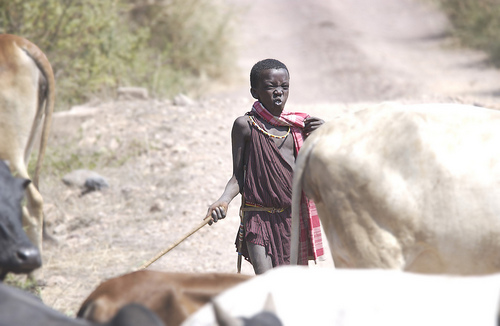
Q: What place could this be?
A: It is a road.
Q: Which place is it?
A: It is a road.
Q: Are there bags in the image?
A: No, there are no bags.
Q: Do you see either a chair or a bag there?
A: No, there are no bags or chairs.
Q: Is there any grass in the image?
A: Yes, there is grass.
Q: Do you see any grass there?
A: Yes, there is grass.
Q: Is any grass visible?
A: Yes, there is grass.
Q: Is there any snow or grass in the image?
A: Yes, there is grass.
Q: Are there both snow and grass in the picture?
A: No, there is grass but no snow.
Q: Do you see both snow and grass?
A: No, there is grass but no snow.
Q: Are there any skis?
A: No, there are no skis.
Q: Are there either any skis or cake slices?
A: No, there are no skis or cake slices.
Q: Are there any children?
A: Yes, there is a child.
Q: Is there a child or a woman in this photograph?
A: Yes, there is a child.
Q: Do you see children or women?
A: Yes, there is a child.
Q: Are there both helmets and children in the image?
A: No, there is a child but no helmets.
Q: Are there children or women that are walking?
A: Yes, the child is walking.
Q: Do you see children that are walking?
A: Yes, there is a child that is walking.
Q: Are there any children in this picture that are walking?
A: Yes, there is a child that is walking.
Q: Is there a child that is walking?
A: Yes, there is a child that is walking.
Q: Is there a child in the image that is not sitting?
A: Yes, there is a child that is walking.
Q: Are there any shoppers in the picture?
A: No, there are no shoppers.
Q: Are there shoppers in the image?
A: No, there are no shoppers.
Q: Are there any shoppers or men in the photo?
A: No, there are no shoppers or men.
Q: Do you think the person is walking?
A: Yes, the child is walking.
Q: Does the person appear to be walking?
A: Yes, the child is walking.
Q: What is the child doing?
A: The child is walking.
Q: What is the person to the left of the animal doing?
A: The child is walking.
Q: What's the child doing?
A: The child is walking.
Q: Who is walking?
A: The child is walking.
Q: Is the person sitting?
A: No, the kid is walking.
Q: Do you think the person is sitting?
A: No, the kid is walking.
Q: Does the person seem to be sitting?
A: No, the kid is walking.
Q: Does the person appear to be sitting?
A: No, the kid is walking.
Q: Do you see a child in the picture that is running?
A: No, there is a child but he is walking.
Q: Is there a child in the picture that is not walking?
A: No, there is a child but he is walking.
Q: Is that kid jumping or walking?
A: The kid is walking.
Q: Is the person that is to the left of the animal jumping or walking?
A: The kid is walking.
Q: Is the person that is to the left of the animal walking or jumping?
A: The kid is walking.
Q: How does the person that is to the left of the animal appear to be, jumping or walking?
A: The kid is walking.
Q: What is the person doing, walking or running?
A: The child is walking.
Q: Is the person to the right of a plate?
A: No, the kid is to the right of the cow.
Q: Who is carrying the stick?
A: The child is carrying the stick.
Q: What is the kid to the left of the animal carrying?
A: The kid is carrying a stick.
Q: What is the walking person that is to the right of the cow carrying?
A: The kid is carrying a stick.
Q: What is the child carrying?
A: The kid is carrying a stick.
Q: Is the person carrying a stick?
A: Yes, the kid is carrying a stick.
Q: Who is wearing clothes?
A: The kid is wearing clothes.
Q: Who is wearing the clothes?
A: The kid is wearing clothes.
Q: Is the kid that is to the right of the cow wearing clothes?
A: Yes, the child is wearing clothes.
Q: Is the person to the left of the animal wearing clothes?
A: Yes, the child is wearing clothes.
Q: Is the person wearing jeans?
A: No, the child is wearing clothes.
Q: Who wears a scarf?
A: The child wears a scarf.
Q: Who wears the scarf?
A: The child wears a scarf.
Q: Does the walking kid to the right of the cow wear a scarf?
A: Yes, the kid wears a scarf.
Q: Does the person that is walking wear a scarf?
A: Yes, the kid wears a scarf.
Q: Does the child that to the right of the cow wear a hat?
A: No, the child wears a scarf.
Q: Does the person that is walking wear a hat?
A: No, the child wears a scarf.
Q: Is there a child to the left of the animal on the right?
A: Yes, there is a child to the left of the animal.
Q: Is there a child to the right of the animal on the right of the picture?
A: No, the child is to the left of the animal.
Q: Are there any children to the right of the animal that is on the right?
A: No, the child is to the left of the animal.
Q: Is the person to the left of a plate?
A: No, the child is to the left of the animal.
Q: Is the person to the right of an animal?
A: No, the child is to the left of an animal.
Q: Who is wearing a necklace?
A: The kid is wearing a necklace.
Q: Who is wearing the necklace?
A: The kid is wearing a necklace.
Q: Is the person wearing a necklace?
A: Yes, the kid is wearing a necklace.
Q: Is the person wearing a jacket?
A: No, the child is wearing a necklace.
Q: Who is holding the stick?
A: The kid is holding the stick.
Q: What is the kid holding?
A: The kid is holding the stick.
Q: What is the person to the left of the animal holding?
A: The kid is holding the stick.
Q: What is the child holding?
A: The kid is holding the stick.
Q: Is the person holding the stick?
A: Yes, the kid is holding the stick.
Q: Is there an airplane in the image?
A: No, there are no airplanes.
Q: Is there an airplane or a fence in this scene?
A: No, there are no airplanes or fences.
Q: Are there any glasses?
A: No, there are no glasses.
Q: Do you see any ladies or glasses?
A: No, there are no glasses or ladies.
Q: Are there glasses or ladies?
A: No, there are no glasses or ladies.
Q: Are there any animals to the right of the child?
A: Yes, there is an animal to the right of the child.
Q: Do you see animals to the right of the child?
A: Yes, there is an animal to the right of the child.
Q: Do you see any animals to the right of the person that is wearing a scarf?
A: Yes, there is an animal to the right of the child.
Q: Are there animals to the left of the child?
A: No, the animal is to the right of the child.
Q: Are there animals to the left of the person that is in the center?
A: No, the animal is to the right of the child.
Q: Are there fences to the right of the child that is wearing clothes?
A: No, there is an animal to the right of the child.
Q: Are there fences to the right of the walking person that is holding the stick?
A: No, there is an animal to the right of the child.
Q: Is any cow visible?
A: Yes, there is a cow.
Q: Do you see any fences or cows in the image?
A: Yes, there is a cow.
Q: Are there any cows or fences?
A: Yes, there is a cow.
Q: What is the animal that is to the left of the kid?
A: The animal is a cow.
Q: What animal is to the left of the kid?
A: The animal is a cow.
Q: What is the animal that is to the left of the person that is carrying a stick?
A: The animal is a cow.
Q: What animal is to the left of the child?
A: The animal is a cow.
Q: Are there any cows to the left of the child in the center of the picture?
A: Yes, there is a cow to the left of the kid.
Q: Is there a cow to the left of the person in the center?
A: Yes, there is a cow to the left of the kid.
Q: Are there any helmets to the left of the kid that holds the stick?
A: No, there is a cow to the left of the kid.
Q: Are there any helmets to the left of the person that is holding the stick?
A: No, there is a cow to the left of the kid.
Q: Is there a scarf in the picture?
A: Yes, there is a scarf.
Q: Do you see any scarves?
A: Yes, there is a scarf.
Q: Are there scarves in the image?
A: Yes, there is a scarf.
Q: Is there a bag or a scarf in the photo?
A: Yes, there is a scarf.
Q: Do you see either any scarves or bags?
A: Yes, there is a scarf.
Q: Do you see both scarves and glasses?
A: No, there is a scarf but no glasses.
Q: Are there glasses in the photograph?
A: No, there are no glasses.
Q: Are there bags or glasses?
A: No, there are no glasses or bags.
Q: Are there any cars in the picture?
A: No, there are no cars.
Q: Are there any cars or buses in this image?
A: No, there are no cars or buses.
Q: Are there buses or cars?
A: No, there are no cars or buses.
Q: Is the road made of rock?
A: Yes, the road is made of rock.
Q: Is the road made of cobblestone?
A: No, the road is made of rock.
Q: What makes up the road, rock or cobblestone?
A: The road is made of rock.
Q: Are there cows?
A: Yes, there is a cow.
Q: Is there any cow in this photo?
A: Yes, there is a cow.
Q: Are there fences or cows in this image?
A: Yes, there is a cow.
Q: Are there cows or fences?
A: Yes, there is a cow.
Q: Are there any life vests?
A: No, there are no life vests.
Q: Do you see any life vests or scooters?
A: No, there are no life vests or scooters.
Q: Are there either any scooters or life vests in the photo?
A: No, there are no life vests or scooters.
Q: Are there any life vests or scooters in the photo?
A: No, there are no life vests or scooters.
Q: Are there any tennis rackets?
A: No, there are no tennis rackets.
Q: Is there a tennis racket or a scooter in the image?
A: No, there are no rackets or scooters.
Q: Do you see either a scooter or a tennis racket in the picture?
A: No, there are no rackets or scooters.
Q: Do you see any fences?
A: No, there are no fences.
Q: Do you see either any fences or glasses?
A: No, there are no fences or glasses.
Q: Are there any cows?
A: Yes, there is a cow.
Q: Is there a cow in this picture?
A: Yes, there is a cow.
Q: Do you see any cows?
A: Yes, there is a cow.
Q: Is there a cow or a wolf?
A: Yes, there is a cow.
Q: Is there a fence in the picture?
A: No, there are no fences.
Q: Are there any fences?
A: No, there are no fences.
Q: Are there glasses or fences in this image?
A: No, there are no fences or glasses.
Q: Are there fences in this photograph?
A: No, there are no fences.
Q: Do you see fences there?
A: No, there are no fences.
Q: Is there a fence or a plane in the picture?
A: No, there are no fences or airplanes.